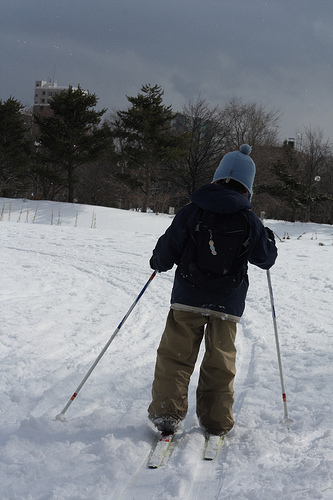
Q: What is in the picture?
A: Snow, a person and skies.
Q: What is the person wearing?
A: Snow gear.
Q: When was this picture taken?
A: During the day.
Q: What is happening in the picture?
A: The person is skiing.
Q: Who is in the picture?
A: A person.